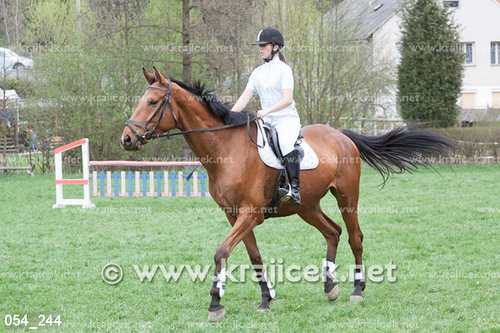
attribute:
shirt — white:
[247, 57, 300, 115]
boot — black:
[276, 147, 303, 204]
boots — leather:
[250, 159, 351, 239]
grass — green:
[3, 176, 497, 331]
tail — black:
[340, 118, 458, 182]